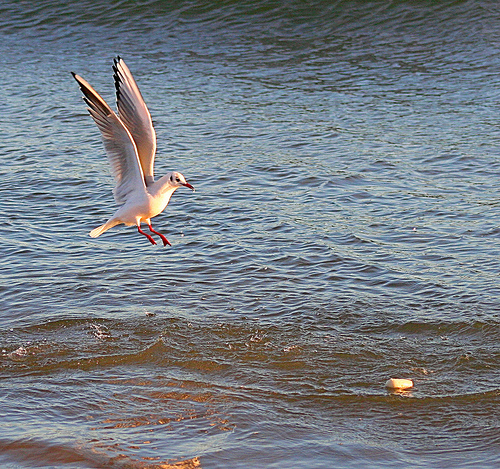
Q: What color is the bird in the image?
A: White.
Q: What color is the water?
A: Blue.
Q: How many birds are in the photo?
A: One.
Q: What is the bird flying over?
A: Water.